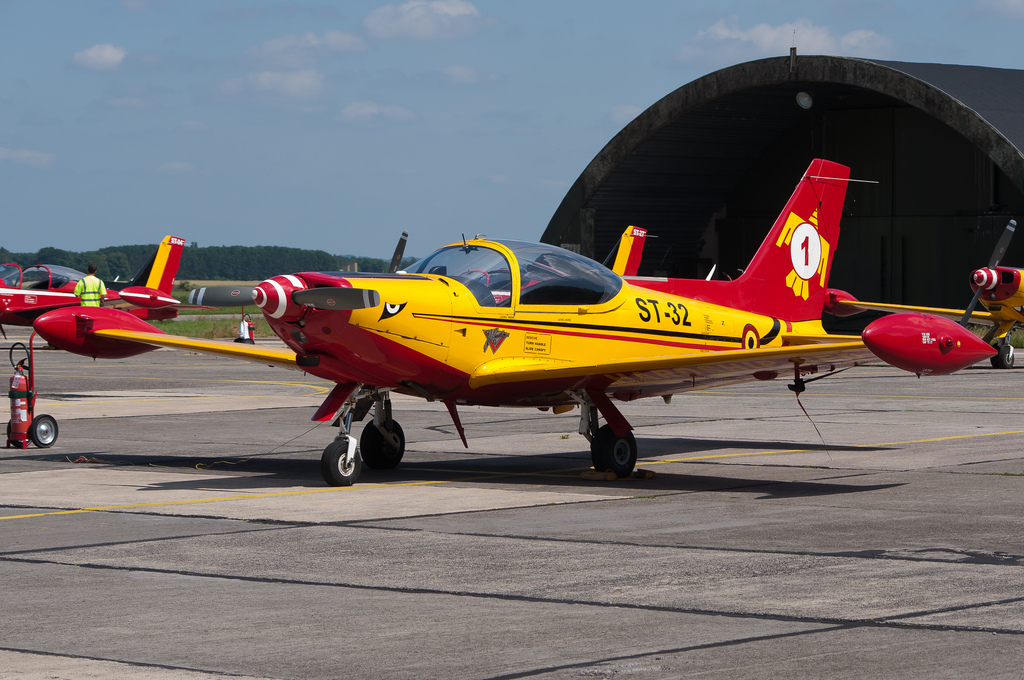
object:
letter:
[647, 292, 668, 326]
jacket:
[71, 273, 111, 306]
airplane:
[0, 230, 219, 333]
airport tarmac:
[0, 328, 1021, 674]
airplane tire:
[588, 420, 640, 478]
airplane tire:
[358, 416, 407, 470]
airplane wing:
[465, 312, 1002, 389]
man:
[71, 261, 111, 309]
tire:
[531, 398, 676, 498]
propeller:
[181, 267, 384, 335]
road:
[375, 501, 1002, 673]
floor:
[440, 486, 755, 649]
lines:
[47, 561, 827, 635]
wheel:
[320, 435, 374, 483]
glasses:
[399, 241, 514, 307]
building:
[536, 41, 1023, 336]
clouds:
[239, 69, 332, 99]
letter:
[633, 296, 653, 322]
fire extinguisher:
[0, 330, 61, 449]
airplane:
[148, 152, 1014, 453]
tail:
[729, 155, 906, 386]